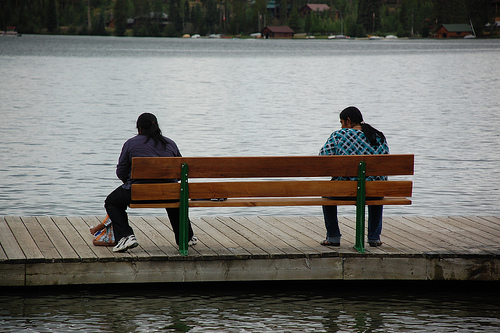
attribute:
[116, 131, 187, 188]
shirt — black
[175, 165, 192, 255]
green pole — Green 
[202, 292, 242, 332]
water — body, large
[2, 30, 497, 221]
water — large, body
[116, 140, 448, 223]
bench — brown, Back 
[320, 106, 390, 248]
woman — wearing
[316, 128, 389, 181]
checkered shirt — blue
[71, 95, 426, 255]
women — sitting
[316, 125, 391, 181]
striped shirt — blue striped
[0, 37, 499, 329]
water — lake, placid body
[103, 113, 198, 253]
woman — wearing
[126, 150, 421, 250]
bench —  back 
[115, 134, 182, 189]
shirt — blue 